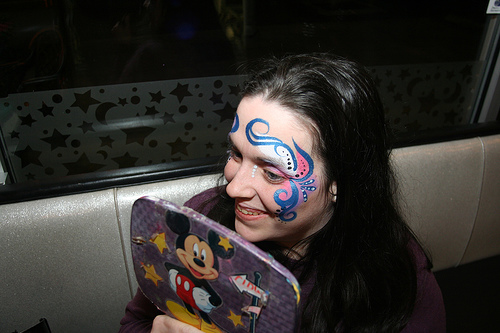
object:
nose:
[226, 157, 258, 198]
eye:
[263, 169, 286, 182]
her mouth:
[235, 203, 272, 223]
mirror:
[130, 196, 302, 333]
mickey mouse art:
[162, 209, 236, 330]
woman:
[117, 52, 445, 333]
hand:
[150, 314, 205, 332]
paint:
[226, 113, 319, 225]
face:
[224, 96, 332, 242]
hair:
[193, 52, 433, 333]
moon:
[95, 102, 118, 126]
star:
[70, 89, 102, 114]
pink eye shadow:
[263, 166, 289, 180]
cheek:
[256, 179, 331, 231]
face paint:
[245, 118, 321, 224]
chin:
[235, 215, 278, 242]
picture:
[0, 0, 499, 333]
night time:
[0, 0, 247, 205]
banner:
[0, 74, 254, 184]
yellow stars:
[142, 264, 163, 286]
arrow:
[229, 275, 272, 306]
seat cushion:
[0, 187, 132, 333]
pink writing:
[235, 275, 260, 293]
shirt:
[118, 183, 446, 333]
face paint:
[227, 112, 239, 161]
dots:
[251, 175, 254, 178]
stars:
[169, 82, 193, 104]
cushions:
[456, 134, 499, 267]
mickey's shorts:
[175, 273, 202, 310]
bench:
[0, 120, 499, 333]